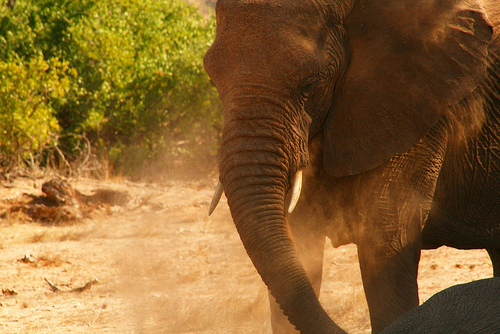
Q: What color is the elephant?
A: The elephant is brown.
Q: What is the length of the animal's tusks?
A: Approximately 7 inches.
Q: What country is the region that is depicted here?
A: South Africa.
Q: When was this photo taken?
A: Noon.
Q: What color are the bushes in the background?
A: Green.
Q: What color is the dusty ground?
A: Light brown.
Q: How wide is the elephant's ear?
A: Two feet.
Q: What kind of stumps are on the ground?
A: They are old tree stumps.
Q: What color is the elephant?
A: A dark brown color.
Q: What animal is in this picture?
A: Elephant.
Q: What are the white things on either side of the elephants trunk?
A: White tusks.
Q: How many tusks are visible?
A: 2.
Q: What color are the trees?
A: Green.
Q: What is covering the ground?
A: Brown dirt.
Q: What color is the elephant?
A: Brown.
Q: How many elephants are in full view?
A: 1.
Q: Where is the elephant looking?
A: Towards ground.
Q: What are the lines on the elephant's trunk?
A: Wrinkles.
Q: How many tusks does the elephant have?
A: Two.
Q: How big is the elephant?
A: Huge.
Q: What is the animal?
A: An elephant.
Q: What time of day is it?
A: Daytime.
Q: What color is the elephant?
A: Brown.